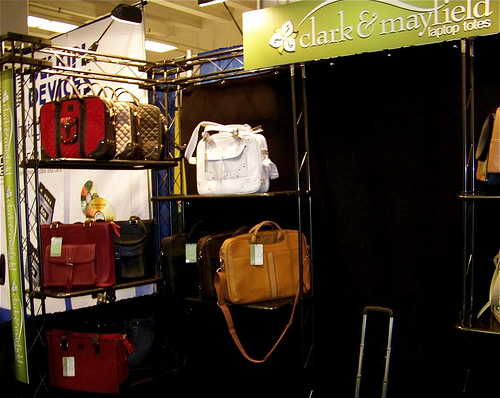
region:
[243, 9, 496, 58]
clark and mayfield laptop tote bags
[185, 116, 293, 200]
white laptop tote bag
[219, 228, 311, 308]
light brown laptop tote bag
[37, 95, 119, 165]
red and black laptop tote bag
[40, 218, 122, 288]
all red laptop tote bag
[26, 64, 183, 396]
shelf of laptop tote bags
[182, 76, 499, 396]
black back cover for laptop tote bags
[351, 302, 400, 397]
roller bag for sales person probably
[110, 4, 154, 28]
lights strategically placed to shine down on bags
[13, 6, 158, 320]
another sales representative next door to laptop tote bag sellers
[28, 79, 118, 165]
The tote is red and brown.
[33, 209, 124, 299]
The tote is red.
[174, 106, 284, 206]
The tote is white.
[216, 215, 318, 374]
The tote is light brown.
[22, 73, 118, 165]
The tote is new.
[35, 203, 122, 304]
The tote is new.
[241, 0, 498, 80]
The sign is green and white.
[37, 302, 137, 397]
The tote is new.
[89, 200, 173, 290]
The tote is new.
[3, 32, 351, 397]
The totes are on display.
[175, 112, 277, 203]
THIS BAG IS BIG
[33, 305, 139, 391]
THIS BAG IS RED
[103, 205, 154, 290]
THIS BAG IS BLACK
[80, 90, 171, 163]
THIS BAG IS TAN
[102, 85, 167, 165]
THIS BAG IS QUILTED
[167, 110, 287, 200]
THIS BAG IS WHITE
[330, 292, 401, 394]
THIS IS A HANDLE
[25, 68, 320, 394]
THESE ARE LAPTOP BAGS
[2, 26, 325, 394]
THIS IS A LAPTOP BAG DISPLAY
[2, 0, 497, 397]
THIS STORE SELLS BAGS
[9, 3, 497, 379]
the scene is in a shop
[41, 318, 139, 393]
the bag is red in colour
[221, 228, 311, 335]
the bag is brown in colour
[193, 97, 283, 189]
the bag is white in colour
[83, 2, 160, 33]
the light is on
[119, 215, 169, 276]
the bag is black in colour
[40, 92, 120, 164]
the bag is red and black in colour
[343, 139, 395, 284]
the wall is black in colour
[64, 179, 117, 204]
the board is white in colour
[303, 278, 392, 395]
the bag has an handlr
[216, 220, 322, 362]
brown leather lap top case for sale and display in a shop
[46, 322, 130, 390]
red briefcase style purse for sale on shelf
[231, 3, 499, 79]
name of store in white letters on green sign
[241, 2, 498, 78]
name of the store reads Clark and Mayfield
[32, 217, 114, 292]
brown leather laptop case with front pocket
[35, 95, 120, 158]
red quilted fabric case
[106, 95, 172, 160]
two leather trimmed laptop cases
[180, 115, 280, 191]
white leather case on top shelf display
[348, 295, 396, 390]
silver top of extended luggage pull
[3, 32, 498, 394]
silver hanging shelves in shop